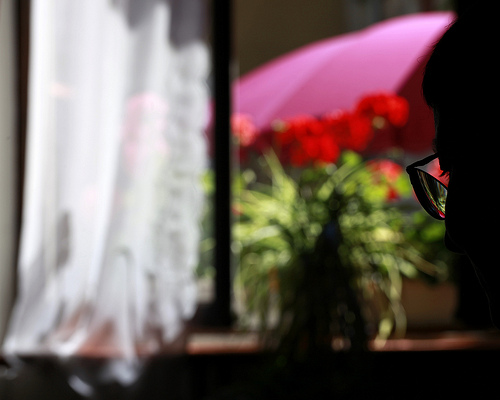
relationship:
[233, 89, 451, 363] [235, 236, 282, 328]
flowers in vase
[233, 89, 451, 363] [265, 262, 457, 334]
flowers in vase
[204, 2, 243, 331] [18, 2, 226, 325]
frame in window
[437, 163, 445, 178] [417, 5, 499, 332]
eyelash of a man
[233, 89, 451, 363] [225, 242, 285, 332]
flowers in vase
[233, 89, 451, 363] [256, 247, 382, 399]
flowers in vase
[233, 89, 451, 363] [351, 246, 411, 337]
flowers in vase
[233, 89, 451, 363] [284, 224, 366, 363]
flowers in vase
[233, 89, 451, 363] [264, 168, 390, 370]
flowers in vase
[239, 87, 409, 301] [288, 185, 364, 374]
flowers in vase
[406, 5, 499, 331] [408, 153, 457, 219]
man wearing eyeglasses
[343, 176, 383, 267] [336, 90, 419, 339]
stem of flower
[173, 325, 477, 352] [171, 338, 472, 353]
light reflecting on wood surface